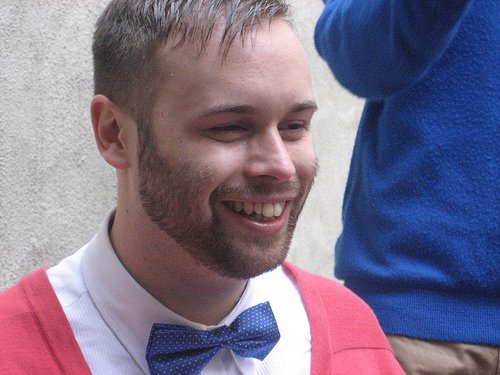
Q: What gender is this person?
A: Male.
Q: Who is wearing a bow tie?
A: A man.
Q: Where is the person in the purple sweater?
A: To the right of the man.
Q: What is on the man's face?
A: A beard.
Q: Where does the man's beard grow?
A: On his face.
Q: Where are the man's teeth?
A: In his mouth.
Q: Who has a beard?
A: The man.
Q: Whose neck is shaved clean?
A: The mans.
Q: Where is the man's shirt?
A: Under the red sweater.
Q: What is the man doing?
A: Smiling.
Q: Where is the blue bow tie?
A: Around the man's neck.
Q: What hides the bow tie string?
A: The man's collar.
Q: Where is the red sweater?
A: On the man.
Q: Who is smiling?
A: The man.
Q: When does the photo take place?
A: During daytime.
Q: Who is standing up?
A: Person in blue shirt.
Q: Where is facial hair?
A: On man's face.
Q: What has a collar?
A: White shirt.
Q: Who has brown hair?
A: A man.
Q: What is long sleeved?
A: Blue shirt.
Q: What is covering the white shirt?
A: Pink sweater.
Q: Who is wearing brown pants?
A: Person standing.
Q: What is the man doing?
A: Smiling.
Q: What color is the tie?
A: Blue.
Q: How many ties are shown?
A: One.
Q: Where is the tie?
A: On the shirt.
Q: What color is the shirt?
A: White.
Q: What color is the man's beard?
A: Brown.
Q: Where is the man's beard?
A: On the face.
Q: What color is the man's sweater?
A: Red.